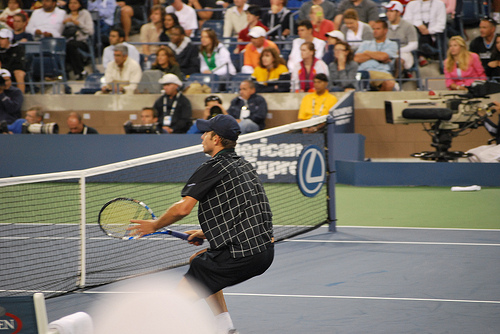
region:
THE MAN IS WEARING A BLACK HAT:
[190, 107, 240, 147]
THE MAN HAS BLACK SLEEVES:
[172, 160, 228, 201]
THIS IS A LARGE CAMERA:
[376, 80, 498, 162]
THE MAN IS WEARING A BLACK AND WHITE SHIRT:
[165, 138, 290, 253]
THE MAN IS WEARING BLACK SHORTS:
[163, 237, 283, 303]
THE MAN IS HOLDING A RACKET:
[81, 188, 199, 256]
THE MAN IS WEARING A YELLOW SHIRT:
[291, 85, 344, 135]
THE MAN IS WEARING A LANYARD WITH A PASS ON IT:
[148, 90, 190, 130]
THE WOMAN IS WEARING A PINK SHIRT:
[433, 42, 483, 90]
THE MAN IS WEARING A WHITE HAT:
[152, 70, 199, 90]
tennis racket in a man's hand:
[94, 196, 206, 246]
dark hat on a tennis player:
[193, 113, 244, 144]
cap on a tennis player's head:
[195, 114, 246, 139]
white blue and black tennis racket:
[96, 194, 205, 243]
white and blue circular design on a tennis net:
[296, 144, 329, 198]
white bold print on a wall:
[230, 138, 302, 180]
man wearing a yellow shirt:
[296, 71, 338, 118]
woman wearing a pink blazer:
[441, 33, 486, 88]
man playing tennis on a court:
[95, 113, 275, 333]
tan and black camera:
[382, 80, 499, 163]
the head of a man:
[174, 99, 289, 171]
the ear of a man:
[205, 125, 227, 150]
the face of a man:
[192, 120, 219, 155]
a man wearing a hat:
[171, 98, 277, 150]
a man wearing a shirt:
[158, 109, 303, 261]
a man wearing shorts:
[151, 202, 317, 303]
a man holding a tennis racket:
[91, 97, 278, 268]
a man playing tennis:
[46, 97, 304, 316]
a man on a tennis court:
[118, 21, 422, 325]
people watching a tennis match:
[39, 2, 381, 144]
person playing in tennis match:
[10, 78, 319, 333]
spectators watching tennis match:
[11, 8, 442, 168]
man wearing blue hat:
[195, 101, 250, 139]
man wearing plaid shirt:
[181, 150, 283, 262]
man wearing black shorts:
[162, 228, 279, 302]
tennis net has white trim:
[7, 106, 341, 293]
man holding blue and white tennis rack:
[79, 173, 196, 260]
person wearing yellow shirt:
[298, 84, 335, 128]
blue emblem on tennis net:
[282, 136, 334, 204]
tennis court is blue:
[248, 212, 483, 324]